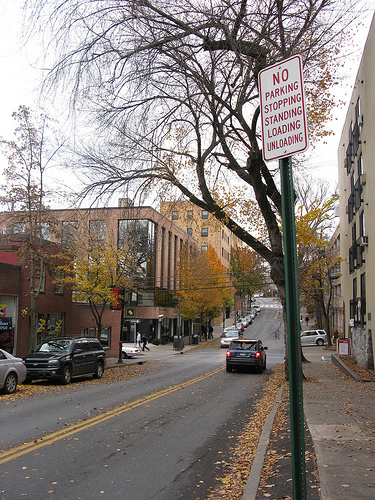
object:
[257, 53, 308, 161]
sign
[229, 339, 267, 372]
car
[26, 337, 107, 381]
car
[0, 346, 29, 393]
car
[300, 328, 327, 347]
car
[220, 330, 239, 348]
car